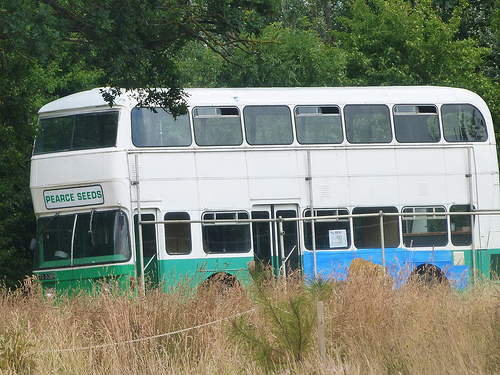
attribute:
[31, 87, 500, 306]
bus — double-decker, green, blue, painted, white, large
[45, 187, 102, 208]
letters — green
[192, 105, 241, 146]
window — open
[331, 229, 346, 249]
object — white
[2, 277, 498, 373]
grass — green, overgrown